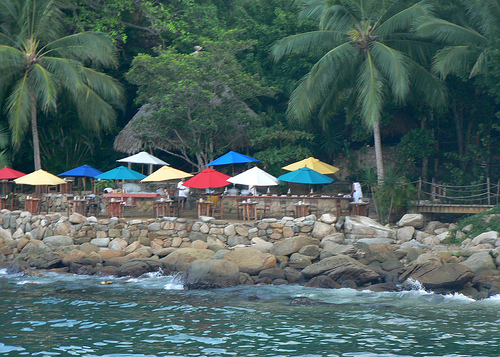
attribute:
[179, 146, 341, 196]
umbrellas — blue, yellow, lined up, colored, open, colorful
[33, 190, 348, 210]
tables — wooden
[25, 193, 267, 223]
chairs — wooden, wood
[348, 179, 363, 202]
person — standing, preparing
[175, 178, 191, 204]
person — standing, preparing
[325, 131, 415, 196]
hut — thatched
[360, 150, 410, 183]
wall — rock, stone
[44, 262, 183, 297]
waves — splashing, crashing, breaking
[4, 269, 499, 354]
ocean — dark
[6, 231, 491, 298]
rocks — wet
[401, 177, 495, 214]
bridge — wood, wooden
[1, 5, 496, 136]
palms — tall, green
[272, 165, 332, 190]
umbrella — blue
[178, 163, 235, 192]
umbrella — red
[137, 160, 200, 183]
umbrella — yellow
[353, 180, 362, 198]
uniform — white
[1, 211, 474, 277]
wall — stone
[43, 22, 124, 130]
leaves — green, long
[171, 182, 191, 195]
shirt — white